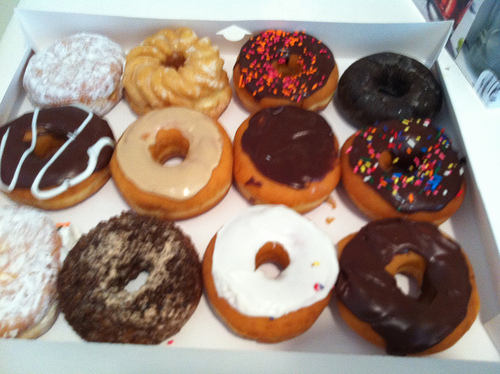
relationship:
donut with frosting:
[202, 202, 340, 346] [361, 226, 475, 335]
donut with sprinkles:
[202, 202, 340, 346] [382, 154, 453, 181]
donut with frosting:
[202, 202, 340, 336] [230, 214, 315, 304]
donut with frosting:
[202, 202, 340, 346] [134, 130, 221, 181]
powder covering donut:
[39, 30, 119, 103] [17, 29, 128, 117]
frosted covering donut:
[350, 227, 460, 329] [234, 104, 360, 219]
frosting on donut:
[132, 106, 208, 191] [106, 101, 236, 218]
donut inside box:
[202, 202, 340, 346] [325, 11, 386, 49]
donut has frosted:
[202, 202, 340, 346] [208, 201, 345, 322]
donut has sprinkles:
[202, 202, 340, 346] [404, 129, 427, 145]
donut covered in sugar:
[202, 202, 340, 346] [2, 215, 45, 306]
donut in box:
[202, 202, 340, 346] [327, 29, 407, 45]